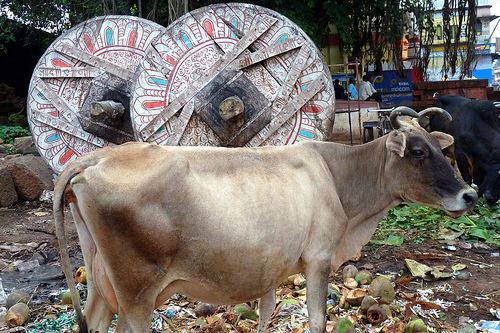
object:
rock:
[0, 150, 52, 209]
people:
[332, 75, 378, 102]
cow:
[52, 106, 480, 333]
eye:
[409, 148, 427, 158]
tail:
[46, 159, 92, 333]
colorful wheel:
[128, 2, 334, 149]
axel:
[218, 95, 245, 123]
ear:
[429, 130, 455, 149]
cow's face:
[385, 124, 479, 220]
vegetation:
[10, 260, 472, 331]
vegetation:
[365, 200, 499, 243]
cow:
[425, 91, 497, 203]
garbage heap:
[5, 271, 423, 332]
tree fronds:
[465, 0, 481, 79]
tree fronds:
[453, 0, 464, 73]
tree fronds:
[387, 1, 405, 76]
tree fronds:
[368, 0, 384, 77]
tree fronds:
[441, 1, 453, 78]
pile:
[371, 196, 497, 245]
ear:
[385, 130, 407, 158]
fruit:
[345, 269, 394, 333]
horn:
[389, 105, 421, 129]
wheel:
[129, 2, 336, 148]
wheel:
[23, 12, 166, 176]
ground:
[0, 70, 500, 333]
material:
[379, 206, 500, 245]